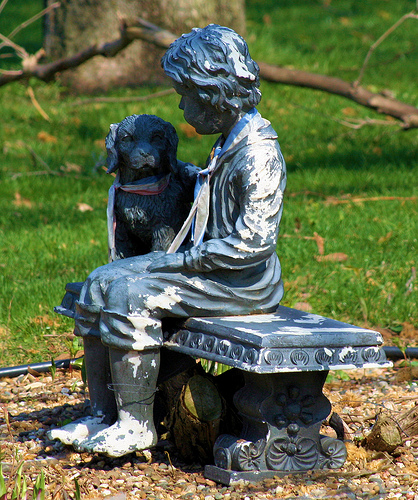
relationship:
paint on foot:
[81, 421, 164, 457] [74, 422, 155, 461]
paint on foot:
[49, 408, 108, 448] [49, 418, 110, 450]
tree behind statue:
[48, 2, 248, 94] [45, 23, 395, 489]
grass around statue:
[1, 1, 416, 369] [45, 23, 395, 489]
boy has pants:
[46, 31, 286, 459] [71, 247, 283, 341]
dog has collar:
[98, 114, 201, 257] [118, 173, 179, 195]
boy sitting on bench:
[46, 31, 286, 459] [59, 285, 392, 487]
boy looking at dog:
[46, 31, 286, 459] [98, 114, 201, 257]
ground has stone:
[2, 4, 411, 500] [32, 385, 39, 395]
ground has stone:
[2, 4, 411, 500] [8, 403, 19, 415]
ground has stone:
[2, 4, 411, 500] [13, 448, 27, 458]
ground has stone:
[2, 4, 411, 500] [42, 470, 56, 474]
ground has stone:
[2, 4, 411, 500] [110, 476, 125, 491]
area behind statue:
[249, 7, 415, 99] [70, 19, 326, 371]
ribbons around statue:
[185, 153, 230, 231] [136, 36, 309, 315]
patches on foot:
[101, 408, 154, 457] [77, 414, 163, 464]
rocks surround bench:
[0, 369, 416, 498] [59, 285, 392, 487]